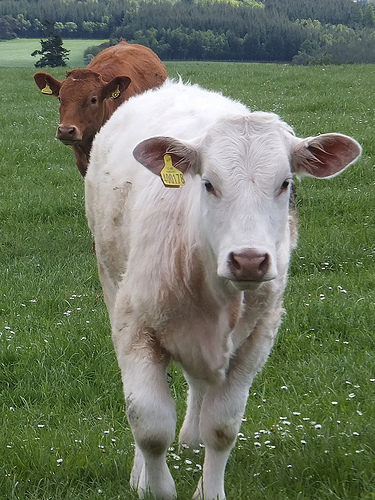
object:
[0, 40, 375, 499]
pasture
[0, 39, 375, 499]
wild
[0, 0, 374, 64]
bushes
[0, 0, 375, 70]
trees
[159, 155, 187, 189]
tag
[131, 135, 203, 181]
ear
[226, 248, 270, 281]
nose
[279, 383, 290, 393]
flowers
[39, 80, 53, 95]
tag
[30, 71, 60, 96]
ear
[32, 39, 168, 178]
cow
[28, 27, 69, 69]
plants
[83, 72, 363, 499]
cow